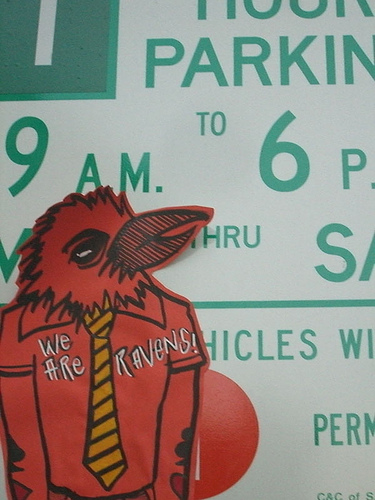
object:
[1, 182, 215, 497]
bird mascot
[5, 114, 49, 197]
number nine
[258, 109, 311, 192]
number six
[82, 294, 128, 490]
tie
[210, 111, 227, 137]
letters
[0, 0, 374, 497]
scene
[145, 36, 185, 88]
letter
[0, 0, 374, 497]
sign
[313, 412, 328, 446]
letter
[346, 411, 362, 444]
letter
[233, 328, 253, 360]
letter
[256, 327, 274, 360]
letter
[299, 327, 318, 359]
letter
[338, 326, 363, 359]
letter